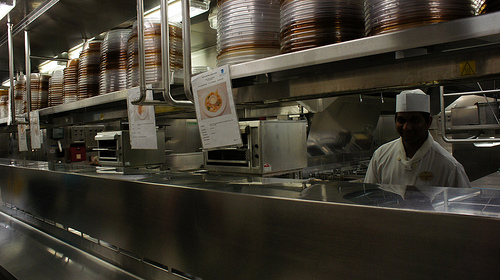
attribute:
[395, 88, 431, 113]
hat — white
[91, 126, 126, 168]
oven — steel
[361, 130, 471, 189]
shirt — white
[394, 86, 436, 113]
hat — paper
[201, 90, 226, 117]
plate — round  and white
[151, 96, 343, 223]
microwave — silver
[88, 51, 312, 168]
paper — rectangular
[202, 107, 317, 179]
kitchen oven — shiny, metal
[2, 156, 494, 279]
steel — stainless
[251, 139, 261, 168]
knob — black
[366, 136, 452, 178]
scarf — white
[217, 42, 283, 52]
plate — stacked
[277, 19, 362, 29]
plate — stacked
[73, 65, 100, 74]
plate — stacked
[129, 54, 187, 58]
plate — stacked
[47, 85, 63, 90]
plate — stacked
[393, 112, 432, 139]
face — person's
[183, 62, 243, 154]
sign — hanging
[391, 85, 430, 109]
hat — white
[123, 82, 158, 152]
sign — white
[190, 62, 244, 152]
sign — white